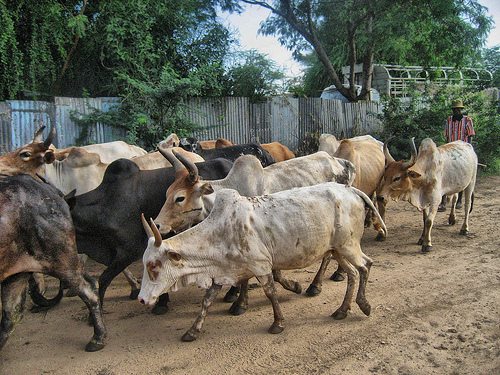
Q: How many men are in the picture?
A: One.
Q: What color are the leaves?
A: Green.